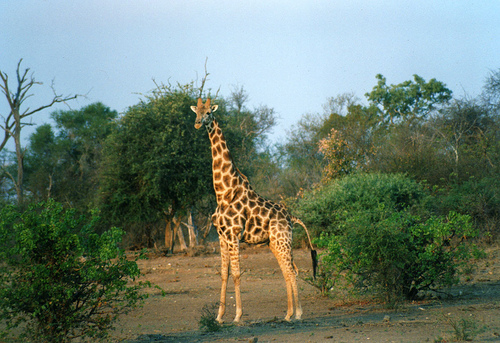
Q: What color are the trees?
A: Green.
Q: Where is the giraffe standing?
A: On the ground.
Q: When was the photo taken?
A: Daytime.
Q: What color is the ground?
A: Brown.